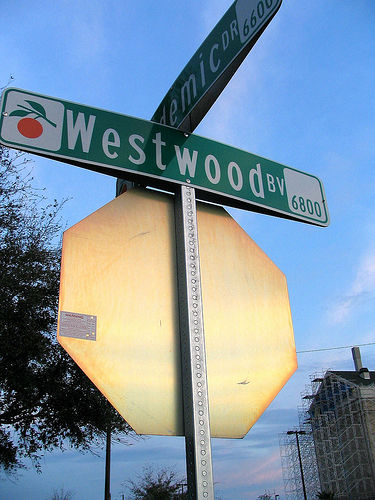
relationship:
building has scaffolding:
[307, 346, 374, 499] [276, 366, 373, 500]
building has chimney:
[307, 346, 374, 499] [351, 346, 363, 371]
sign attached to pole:
[57, 185, 299, 441] [174, 185, 216, 499]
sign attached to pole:
[2, 85, 329, 228] [174, 185, 216, 499]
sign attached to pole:
[115, 3, 283, 197] [174, 185, 216, 499]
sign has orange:
[2, 85, 329, 228] [8, 101, 59, 140]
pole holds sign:
[174, 185, 216, 499] [57, 185, 299, 441]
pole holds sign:
[174, 185, 216, 499] [2, 85, 329, 228]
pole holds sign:
[174, 185, 216, 499] [115, 3, 283, 197]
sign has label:
[57, 185, 299, 441] [58, 309, 99, 343]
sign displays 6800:
[2, 85, 329, 228] [289, 194, 323, 218]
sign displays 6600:
[115, 3, 283, 197] [241, 1, 275, 38]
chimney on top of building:
[351, 346, 363, 371] [307, 346, 374, 499]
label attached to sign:
[58, 309, 99, 343] [57, 185, 299, 441]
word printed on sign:
[65, 110, 266, 200] [2, 85, 329, 228]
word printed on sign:
[265, 174, 286, 196] [2, 85, 329, 228]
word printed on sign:
[157, 43, 222, 127] [115, 3, 283, 197]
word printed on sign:
[220, 19, 242, 51] [115, 3, 283, 197]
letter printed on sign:
[67, 109, 99, 153] [2, 85, 329, 228]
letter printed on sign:
[173, 144, 200, 178] [2, 85, 329, 228]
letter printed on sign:
[102, 128, 121, 159] [2, 85, 329, 228]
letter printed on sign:
[167, 99, 179, 127] [115, 3, 283, 197]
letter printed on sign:
[126, 133, 147, 166] [2, 85, 329, 228]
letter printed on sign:
[151, 131, 167, 171] [2, 85, 329, 228]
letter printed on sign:
[203, 154, 223, 186] [2, 85, 329, 228]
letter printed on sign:
[226, 162, 246, 193] [2, 85, 329, 228]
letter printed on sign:
[247, 162, 267, 201] [2, 85, 329, 228]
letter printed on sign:
[220, 30, 232, 51] [115, 3, 283, 197]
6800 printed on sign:
[289, 194, 323, 218] [2, 85, 329, 228]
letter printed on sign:
[179, 74, 200, 114] [115, 3, 283, 197]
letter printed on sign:
[197, 51, 208, 88] [115, 3, 283, 197]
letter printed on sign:
[208, 43, 223, 72] [115, 3, 283, 197]